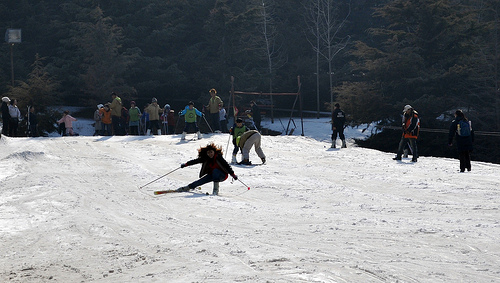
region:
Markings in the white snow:
[71, 202, 301, 281]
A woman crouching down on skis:
[146, 143, 256, 197]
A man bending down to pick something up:
[228, 128, 264, 168]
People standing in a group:
[91, 93, 173, 133]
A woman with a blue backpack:
[446, 106, 481, 169]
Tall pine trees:
[51, 2, 211, 97]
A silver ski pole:
[228, 175, 255, 191]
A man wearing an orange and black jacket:
[401, 102, 423, 161]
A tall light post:
[1, 25, 29, 86]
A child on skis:
[171, 101, 213, 138]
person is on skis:
[162, 123, 257, 215]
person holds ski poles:
[138, 141, 255, 204]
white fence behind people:
[242, 103, 337, 148]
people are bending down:
[240, 106, 268, 177]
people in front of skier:
[220, 131, 265, 162]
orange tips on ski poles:
[243, 183, 260, 188]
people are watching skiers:
[80, 80, 235, 131]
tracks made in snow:
[75, 165, 295, 282]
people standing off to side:
[310, 93, 497, 193]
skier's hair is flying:
[185, 128, 240, 204]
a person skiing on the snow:
[117, 143, 241, 203]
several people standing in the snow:
[66, 73, 278, 144]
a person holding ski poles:
[113, 151, 240, 217]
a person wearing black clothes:
[326, 92, 357, 159]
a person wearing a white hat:
[396, 96, 425, 123]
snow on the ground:
[22, 154, 402, 276]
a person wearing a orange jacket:
[94, 99, 115, 135]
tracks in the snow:
[311, 172, 428, 281]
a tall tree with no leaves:
[301, 11, 348, 123]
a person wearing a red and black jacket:
[384, 96, 435, 163]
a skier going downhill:
[128, 145, 253, 201]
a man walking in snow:
[393, 99, 423, 166]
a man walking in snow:
[443, 106, 480, 173]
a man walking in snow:
[321, 97, 351, 157]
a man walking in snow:
[201, 86, 223, 133]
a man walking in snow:
[141, 95, 161, 132]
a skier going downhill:
[167, 99, 215, 144]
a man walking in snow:
[6, 94, 23, 140]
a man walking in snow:
[103, 91, 125, 133]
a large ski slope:
[9, 134, 496, 281]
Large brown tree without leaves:
[309, 4, 345, 98]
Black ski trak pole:
[141, 163, 181, 187]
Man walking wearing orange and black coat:
[399, 103, 420, 163]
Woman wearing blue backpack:
[448, 108, 476, 170]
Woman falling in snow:
[181, 143, 234, 198]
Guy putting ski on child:
[226, 119, 267, 167]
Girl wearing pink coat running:
[58, 108, 81, 136]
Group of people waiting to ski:
[96, 95, 170, 132]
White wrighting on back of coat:
[334, 111, 345, 120]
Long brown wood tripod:
[226, 78, 315, 104]